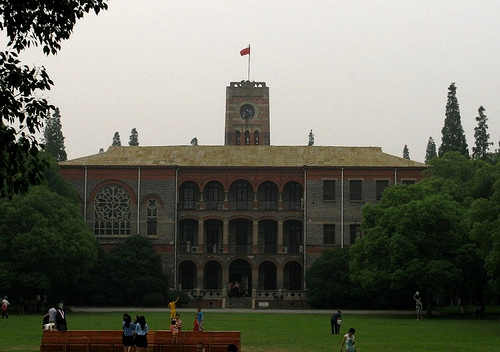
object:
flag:
[239, 45, 253, 80]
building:
[55, 53, 429, 308]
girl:
[133, 316, 150, 352]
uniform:
[135, 323, 148, 347]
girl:
[122, 316, 135, 349]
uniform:
[120, 321, 135, 346]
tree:
[439, 81, 469, 155]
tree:
[39, 100, 67, 161]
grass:
[0, 312, 498, 352]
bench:
[37, 330, 243, 352]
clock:
[238, 102, 256, 121]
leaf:
[42, 44, 51, 58]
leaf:
[13, 43, 25, 54]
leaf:
[93, 1, 101, 16]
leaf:
[54, 40, 62, 54]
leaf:
[40, 71, 50, 79]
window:
[322, 178, 335, 200]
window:
[348, 178, 361, 201]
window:
[374, 180, 388, 202]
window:
[322, 221, 336, 247]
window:
[349, 224, 361, 247]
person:
[338, 326, 360, 351]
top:
[134, 323, 149, 337]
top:
[122, 321, 134, 335]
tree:
[344, 147, 500, 317]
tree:
[99, 232, 166, 305]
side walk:
[62, 303, 444, 314]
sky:
[3, 0, 499, 144]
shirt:
[168, 301, 176, 309]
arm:
[173, 296, 180, 304]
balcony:
[179, 181, 302, 211]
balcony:
[176, 216, 304, 255]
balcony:
[179, 258, 301, 298]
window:
[87, 180, 134, 236]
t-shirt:
[3, 300, 9, 308]